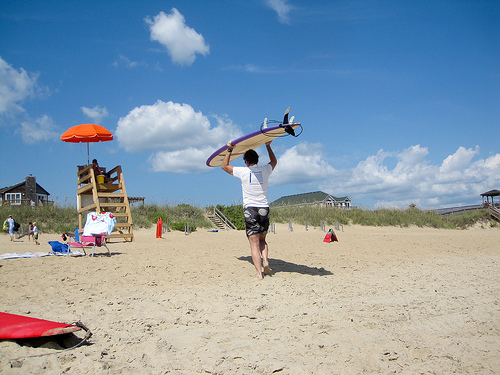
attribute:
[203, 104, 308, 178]
surfboard — white, blue, purple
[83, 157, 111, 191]
lifeguard — sitting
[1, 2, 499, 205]
sky — blue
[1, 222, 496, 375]
ground — sandy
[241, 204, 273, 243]
shorts — dark, black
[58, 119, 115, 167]
umbrella — open, orange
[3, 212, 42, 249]
family — walking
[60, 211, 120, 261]
chair — sitting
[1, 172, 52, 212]
house — in the distance, in distance, brown, white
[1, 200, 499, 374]
beach — tan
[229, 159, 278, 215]
shirt — white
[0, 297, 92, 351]
surfboard — red, on left side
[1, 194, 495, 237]
grass — green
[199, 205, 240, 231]
steps — leading away, leaving beach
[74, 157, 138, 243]
chair — wooden